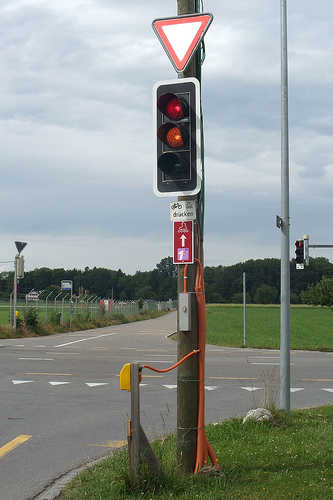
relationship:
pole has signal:
[171, 1, 210, 472] [156, 79, 205, 196]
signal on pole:
[156, 79, 205, 196] [171, 1, 210, 472]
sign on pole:
[149, 12, 210, 75] [171, 1, 210, 472]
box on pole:
[178, 290, 197, 337] [171, 1, 210, 472]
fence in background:
[0, 284, 173, 327] [0, 243, 331, 364]